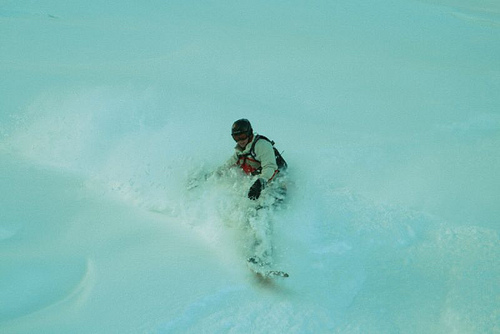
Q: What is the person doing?
A: Skiing.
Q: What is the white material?
A: Snow.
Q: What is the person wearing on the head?
A: Hat.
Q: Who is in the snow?
A: Person wearing skis.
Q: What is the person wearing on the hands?
A: Gloves.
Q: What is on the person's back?
A: Backpack.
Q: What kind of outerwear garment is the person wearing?
A: Tan coat.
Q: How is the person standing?
A: Bent at the knees.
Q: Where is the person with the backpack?
A: Snow.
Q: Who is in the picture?
A: A man is snowboarding.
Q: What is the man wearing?
A: A helmet and jacket.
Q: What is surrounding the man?
A: Snow on the mountain.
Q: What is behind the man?
A: Snow on the mountain.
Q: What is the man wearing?
A: A snowsuit.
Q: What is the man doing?
A: Snowboarding down a mountain.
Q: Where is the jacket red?
A: On the front and a sleeve.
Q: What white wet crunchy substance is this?
A: Snow.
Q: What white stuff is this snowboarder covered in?
A: Snow.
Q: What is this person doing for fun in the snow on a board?
A: Snowboarding.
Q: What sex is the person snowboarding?
A: Female.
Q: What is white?
A: Snow.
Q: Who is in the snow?
A: Snowboarder.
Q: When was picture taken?
A: Winter.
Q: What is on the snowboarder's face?
A: Goggles.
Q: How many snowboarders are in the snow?
A: One.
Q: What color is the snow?
A: White.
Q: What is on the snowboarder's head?
A: Cap.